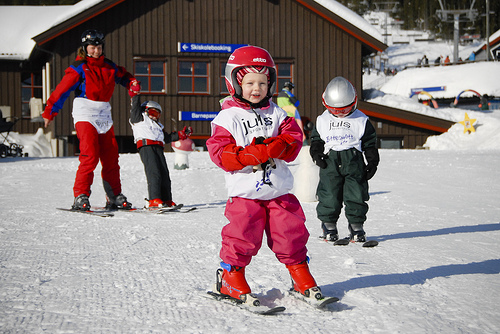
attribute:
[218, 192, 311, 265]
snow pants — red, pink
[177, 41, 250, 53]
sign — blue, white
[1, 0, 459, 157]
building — brown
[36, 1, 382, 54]
stripe — orange, red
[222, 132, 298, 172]
mittens — red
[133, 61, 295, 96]
windows — red framed, four paned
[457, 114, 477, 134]
star — yellow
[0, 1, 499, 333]
snow — white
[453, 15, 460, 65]
pole — gray, metal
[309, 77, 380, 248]
skier — young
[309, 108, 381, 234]
suit — green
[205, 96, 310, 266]
suit — bright pink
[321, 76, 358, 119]
helmet — silver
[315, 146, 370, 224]
snow pants — green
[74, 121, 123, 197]
snow pants — red